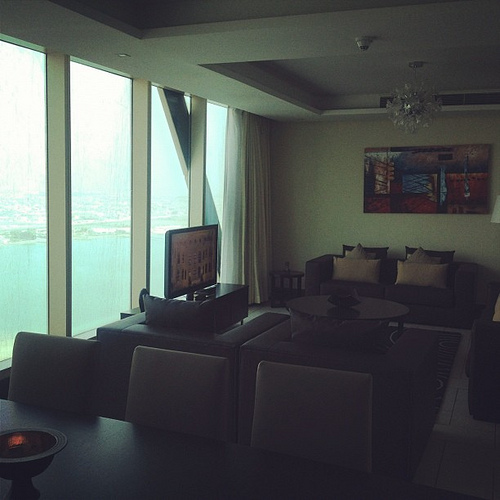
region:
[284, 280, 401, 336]
table in center of room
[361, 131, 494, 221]
picture on the wall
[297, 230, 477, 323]
couch in the room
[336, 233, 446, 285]
pillows on the couch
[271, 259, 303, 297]
table by the couch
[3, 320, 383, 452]
backs of three chairs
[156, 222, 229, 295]
screen on a table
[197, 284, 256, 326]
table with screen on it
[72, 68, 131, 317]
long window in room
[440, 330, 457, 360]
rug in center of room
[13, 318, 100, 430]
Chair at a table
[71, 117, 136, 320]
Window overlooking blue water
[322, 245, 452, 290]
Pillows on a couch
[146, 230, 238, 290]
Monitor facing a room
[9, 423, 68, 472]
Bowl on a table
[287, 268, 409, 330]
Round wooden coffee table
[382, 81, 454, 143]
Light hanging from a ceiling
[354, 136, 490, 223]
Picture hanging on a wall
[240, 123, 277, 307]
Curtain at the side of a window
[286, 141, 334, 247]
Yellow wall at the end of a room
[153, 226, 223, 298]
A TV on a table.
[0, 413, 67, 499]
A round bowl on a table.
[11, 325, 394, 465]
Three chairs at a table.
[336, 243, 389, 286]
Three pillows on sofa.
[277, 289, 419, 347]
A coffee table in the center of the room.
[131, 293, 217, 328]
A pillow on a chair.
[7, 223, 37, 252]
The shore can be seen through the window.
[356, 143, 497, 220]
A painting on the wall.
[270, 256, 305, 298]
A small side table with something on it.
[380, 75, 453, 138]
A chandilier dangles from the ceiling.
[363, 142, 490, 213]
large painting on the wall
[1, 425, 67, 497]
round candy dish on the table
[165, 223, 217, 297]
large flat television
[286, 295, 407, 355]
large round coffee table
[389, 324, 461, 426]
part of bacl area rug with white circles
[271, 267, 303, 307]
small round end table next to couch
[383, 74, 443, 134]
glass round chandelier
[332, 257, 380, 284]
long tan pillow on the couch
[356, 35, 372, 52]
white security camera on the ceiling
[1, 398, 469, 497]
part of dining room table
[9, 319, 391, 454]
three leather grey kitchen chairs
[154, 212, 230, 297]
black tv on the stand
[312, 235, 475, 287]
decorative pillow in the couch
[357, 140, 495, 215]
colorful painting in the wall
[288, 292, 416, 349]
round glass top center table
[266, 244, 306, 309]
round side table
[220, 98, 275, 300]
white long curtains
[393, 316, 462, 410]
dark accent rug in the floor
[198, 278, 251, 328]
brown television stand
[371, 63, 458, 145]
glass chandelier in the living room